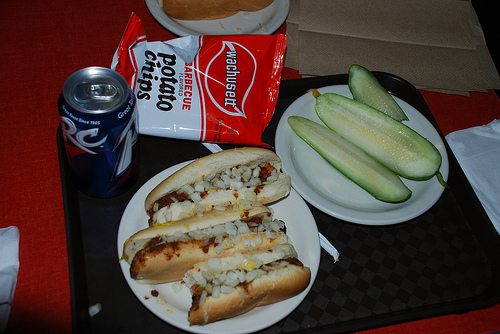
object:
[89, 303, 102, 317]
onion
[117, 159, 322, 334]
plate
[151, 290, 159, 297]
chili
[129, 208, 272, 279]
chili dog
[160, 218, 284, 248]
onion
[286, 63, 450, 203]
pickle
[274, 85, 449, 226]
plate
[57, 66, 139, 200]
can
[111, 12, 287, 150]
bag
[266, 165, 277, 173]
hot dog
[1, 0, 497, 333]
table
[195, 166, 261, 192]
onion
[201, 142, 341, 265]
straw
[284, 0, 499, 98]
towels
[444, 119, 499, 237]
napkin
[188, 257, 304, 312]
chili dog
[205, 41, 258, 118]
logo